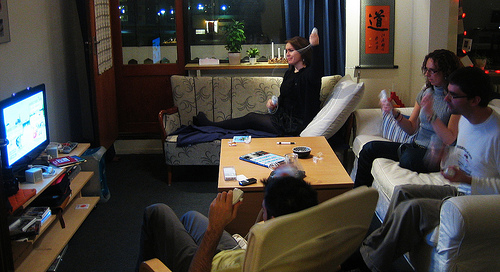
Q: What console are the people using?
A: Nintendo Wii.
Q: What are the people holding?
A: Wii remotes.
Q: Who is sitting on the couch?
A: Two people.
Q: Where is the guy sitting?
A: In white chair.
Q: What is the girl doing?
A: Watching video game.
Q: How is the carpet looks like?
A: Blue.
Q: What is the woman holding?
A: Game controller.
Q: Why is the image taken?
A: Remembrance.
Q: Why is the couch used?
A: Sit.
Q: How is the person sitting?
A: With remote.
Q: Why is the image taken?
A: Remembrance.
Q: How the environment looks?
A: Happy.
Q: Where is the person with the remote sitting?
A: On a couch.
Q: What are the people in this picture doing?
A: Playing a video game.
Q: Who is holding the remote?
A: The girl in the black sweater.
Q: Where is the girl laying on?
A: White sofa.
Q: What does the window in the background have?
A: Black curtain.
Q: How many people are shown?
A: Four.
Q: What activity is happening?
A: Playing video games.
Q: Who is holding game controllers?
A: Everyone.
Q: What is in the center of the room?
A: A coffee table.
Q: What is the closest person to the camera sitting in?
A: A chair.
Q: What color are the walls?
A: White.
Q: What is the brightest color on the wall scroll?
A: Orange.